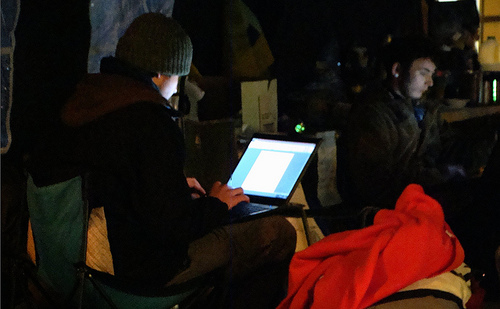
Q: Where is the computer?
A: Lap.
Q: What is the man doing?
A: Looking at the computer screen.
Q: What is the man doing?
A: Working on computer.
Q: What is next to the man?
A: A red blanket.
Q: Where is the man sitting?
A: In a lawn chair.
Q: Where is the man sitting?
A: In a lawn chair.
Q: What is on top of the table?
A: Boxes.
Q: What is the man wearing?
A: A black jacket.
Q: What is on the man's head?
A: A knitted beanie.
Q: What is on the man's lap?
A: A laptop.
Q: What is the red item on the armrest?
A: A coat.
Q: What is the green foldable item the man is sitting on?
A: A folding chair.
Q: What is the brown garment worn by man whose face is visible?
A: A coat.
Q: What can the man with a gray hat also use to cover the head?
A: A hood.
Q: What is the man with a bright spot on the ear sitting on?
A: A chair.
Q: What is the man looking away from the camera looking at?
A: A laptop.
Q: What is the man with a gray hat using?
A: A laptop.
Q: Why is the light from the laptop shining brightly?
A: It is open.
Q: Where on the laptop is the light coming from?
A: The screen.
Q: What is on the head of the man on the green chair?
A: A hat.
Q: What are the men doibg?
A: Working on laptops.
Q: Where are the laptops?
A: On their laps.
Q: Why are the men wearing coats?
A: Because they are cold.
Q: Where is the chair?
A: Under the man.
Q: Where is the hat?
A: On the man's head.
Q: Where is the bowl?
A: On the counter.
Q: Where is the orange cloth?
A: Next to the man in the blue chair.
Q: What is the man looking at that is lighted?
A: A laptop.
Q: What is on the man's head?
A: A cap.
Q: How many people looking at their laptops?
A: Two.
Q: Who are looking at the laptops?
A: Men.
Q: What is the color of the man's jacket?
A: Black.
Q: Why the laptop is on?
A: To do homework.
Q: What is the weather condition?
A: Cold.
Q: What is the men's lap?
A: Laptops.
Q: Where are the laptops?
A: On the men's lap.